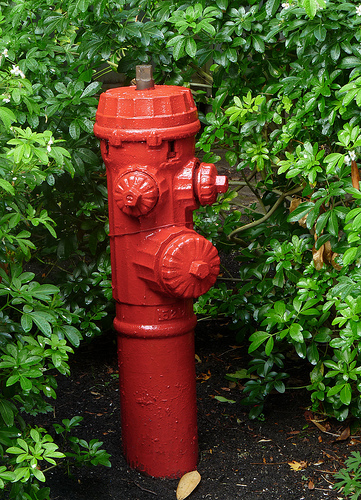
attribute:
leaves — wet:
[0, 259, 84, 401]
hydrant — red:
[75, 58, 236, 370]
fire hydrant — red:
[74, 72, 239, 399]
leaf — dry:
[150, 463, 209, 496]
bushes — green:
[1, 0, 359, 498]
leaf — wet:
[274, 257, 284, 277]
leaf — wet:
[284, 322, 308, 343]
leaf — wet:
[263, 334, 278, 358]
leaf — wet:
[245, 332, 274, 357]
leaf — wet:
[246, 329, 278, 342]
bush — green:
[122, 6, 358, 243]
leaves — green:
[245, 10, 356, 188]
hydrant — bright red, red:
[97, 63, 229, 475]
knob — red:
[212, 170, 230, 193]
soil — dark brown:
[215, 428, 306, 486]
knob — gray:
[132, 61, 157, 91]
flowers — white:
[2, 43, 32, 83]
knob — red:
[189, 261, 210, 278]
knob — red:
[121, 190, 134, 205]